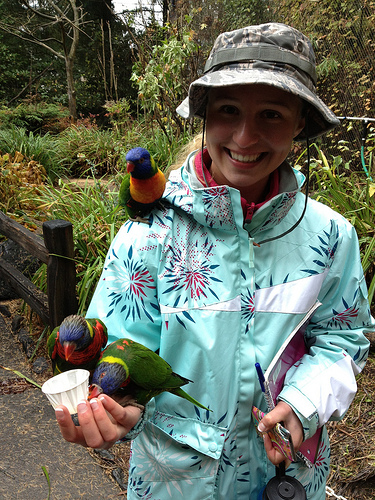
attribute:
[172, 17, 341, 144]
hat — camouflage, camouflage-patterned, green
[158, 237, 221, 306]
design — pink, blue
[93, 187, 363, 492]
coat — trench, pink, blue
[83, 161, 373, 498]
jacket — blue, light blue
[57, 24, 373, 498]
girl — feeding lorikeets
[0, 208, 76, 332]
fence — wooden, small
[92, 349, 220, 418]
lorikeet — rainbow-colored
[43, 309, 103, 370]
lorikeet — rainbow-colored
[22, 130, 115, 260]
plants — green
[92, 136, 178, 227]
bird — green, blue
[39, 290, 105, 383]
bird — green, blue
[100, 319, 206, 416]
bird — green, blue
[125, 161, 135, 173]
beak — red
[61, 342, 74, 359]
beak — red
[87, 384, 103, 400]
beak — red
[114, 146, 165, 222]
parrot — colorful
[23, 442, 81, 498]
stone — flat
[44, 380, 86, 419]
cup — small